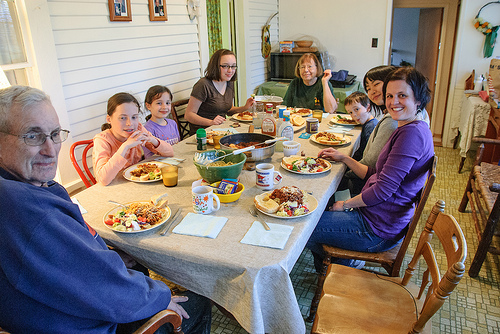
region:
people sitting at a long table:
[2, 48, 434, 331]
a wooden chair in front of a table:
[312, 198, 467, 330]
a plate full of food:
[256, 186, 317, 217]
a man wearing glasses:
[1, 124, 71, 145]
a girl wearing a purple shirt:
[141, 113, 181, 149]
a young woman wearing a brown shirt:
[190, 71, 236, 129]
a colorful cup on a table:
[191, 183, 219, 215]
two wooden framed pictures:
[106, 0, 167, 20]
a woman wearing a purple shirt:
[358, 117, 433, 244]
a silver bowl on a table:
[220, 131, 276, 157]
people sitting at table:
[38, 32, 435, 240]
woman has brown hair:
[388, 61, 429, 106]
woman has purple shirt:
[329, 120, 441, 255]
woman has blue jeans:
[324, 213, 386, 253]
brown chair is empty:
[285, 194, 474, 326]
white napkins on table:
[240, 206, 300, 258]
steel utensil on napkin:
[247, 204, 280, 241]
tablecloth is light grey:
[93, 100, 343, 280]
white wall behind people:
[63, 27, 202, 101]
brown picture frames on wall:
[97, 0, 169, 34]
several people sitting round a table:
[1, 48, 433, 331]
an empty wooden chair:
[290, 198, 467, 333]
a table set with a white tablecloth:
[70, 112, 362, 332]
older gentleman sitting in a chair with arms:
[3, 85, 211, 332]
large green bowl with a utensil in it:
[194, 143, 254, 180]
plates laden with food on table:
[103, 108, 357, 231]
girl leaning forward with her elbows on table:
[91, 92, 174, 184]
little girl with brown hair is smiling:
[145, 85, 180, 145]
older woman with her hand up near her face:
[283, 51, 337, 111]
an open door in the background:
[388, 0, 457, 145]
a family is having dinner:
[3, 22, 483, 331]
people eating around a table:
[6, 2, 443, 325]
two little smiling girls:
[95, 81, 187, 175]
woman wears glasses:
[181, 48, 249, 135]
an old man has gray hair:
[3, 77, 103, 270]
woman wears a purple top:
[334, 63, 446, 255]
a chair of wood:
[309, 204, 473, 329]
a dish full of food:
[100, 187, 178, 238]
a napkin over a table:
[166, 205, 231, 243]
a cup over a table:
[189, 178, 225, 215]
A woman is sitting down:
[312, 66, 433, 252]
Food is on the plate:
[280, 154, 331, 175]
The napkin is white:
[240, 219, 292, 247]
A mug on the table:
[191, 184, 219, 214]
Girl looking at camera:
[91, 90, 171, 183]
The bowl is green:
[190, 150, 240, 180]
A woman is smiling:
[185, 50, 255, 125]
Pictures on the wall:
[107, 0, 165, 20]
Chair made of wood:
[312, 200, 463, 330]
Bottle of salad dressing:
[275, 110, 293, 145]